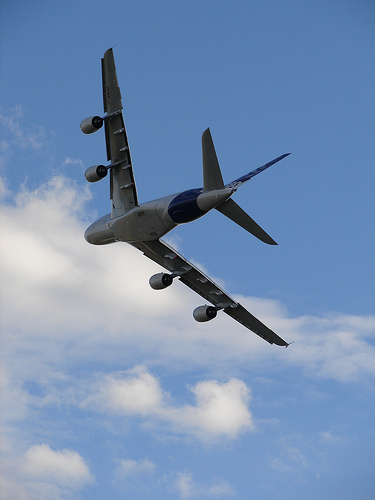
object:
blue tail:
[227, 148, 292, 192]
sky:
[0, 10, 372, 500]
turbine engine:
[78, 115, 104, 134]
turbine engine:
[85, 164, 107, 181]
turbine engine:
[149, 271, 173, 290]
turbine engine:
[192, 305, 217, 322]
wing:
[129, 239, 289, 347]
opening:
[137, 210, 144, 216]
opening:
[147, 231, 158, 237]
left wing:
[85, 46, 141, 207]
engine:
[148, 270, 176, 290]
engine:
[192, 303, 218, 324]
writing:
[100, 64, 109, 112]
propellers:
[72, 103, 234, 341]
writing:
[227, 179, 238, 189]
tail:
[191, 125, 291, 249]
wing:
[196, 123, 224, 189]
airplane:
[69, 36, 298, 360]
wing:
[225, 150, 293, 187]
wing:
[217, 194, 278, 245]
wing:
[196, 121, 228, 187]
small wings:
[158, 109, 301, 271]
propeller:
[77, 157, 118, 191]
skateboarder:
[267, 24, 353, 103]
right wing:
[219, 201, 280, 254]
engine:
[77, 112, 104, 135]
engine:
[81, 160, 108, 180]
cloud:
[80, 366, 169, 423]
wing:
[97, 46, 139, 226]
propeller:
[146, 267, 175, 291]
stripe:
[169, 186, 205, 222]